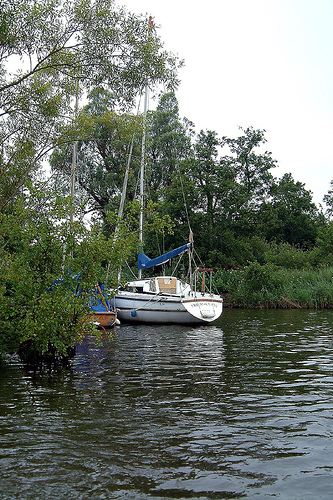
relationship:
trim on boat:
[150, 277, 176, 303] [101, 266, 234, 327]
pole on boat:
[137, 237, 190, 261] [99, 268, 228, 321]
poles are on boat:
[99, 11, 155, 291] [104, 259, 226, 323]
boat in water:
[90, 240, 229, 344] [99, 319, 276, 487]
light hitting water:
[179, 361, 308, 448] [134, 335, 289, 472]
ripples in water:
[149, 359, 218, 403] [130, 358, 274, 432]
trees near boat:
[183, 153, 270, 245] [88, 239, 245, 346]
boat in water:
[106, 243, 224, 324] [111, 334, 309, 497]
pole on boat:
[125, 116, 158, 233] [90, 232, 257, 342]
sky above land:
[213, 40, 283, 92] [12, 45, 321, 448]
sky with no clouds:
[213, 40, 283, 92] [214, 40, 284, 96]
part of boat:
[133, 241, 198, 273] [79, 229, 246, 343]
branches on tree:
[163, 125, 264, 208] [136, 96, 331, 242]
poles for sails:
[101, 48, 205, 339] [83, 91, 256, 385]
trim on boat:
[117, 290, 234, 331] [96, 227, 238, 337]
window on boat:
[111, 281, 155, 301] [91, 274, 232, 343]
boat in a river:
[70, 65, 258, 348] [55, 331, 303, 497]